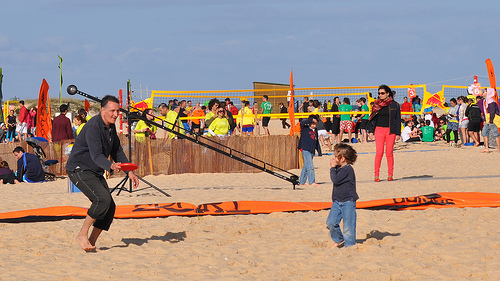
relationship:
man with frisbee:
[64, 98, 129, 233] [119, 149, 141, 178]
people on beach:
[295, 92, 480, 124] [414, 148, 459, 171]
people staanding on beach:
[295, 92, 480, 124] [414, 148, 459, 171]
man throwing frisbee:
[64, 98, 129, 233] [119, 149, 141, 178]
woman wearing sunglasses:
[367, 79, 401, 187] [378, 89, 392, 100]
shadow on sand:
[135, 228, 185, 254] [175, 236, 296, 276]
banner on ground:
[134, 197, 333, 216] [156, 232, 268, 235]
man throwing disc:
[64, 98, 129, 233] [99, 141, 142, 171]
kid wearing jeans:
[333, 142, 390, 255] [332, 194, 370, 256]